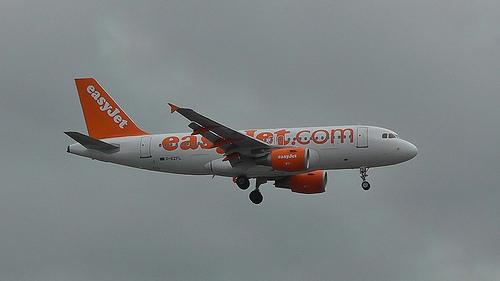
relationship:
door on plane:
[353, 127, 370, 149] [59, 76, 434, 188]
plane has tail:
[59, 76, 420, 205] [88, 80, 128, 130]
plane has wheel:
[59, 76, 434, 188] [246, 188, 264, 206]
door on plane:
[138, 134, 154, 159] [53, 64, 423, 208]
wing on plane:
[171, 109, 276, 161] [48, 86, 380, 209]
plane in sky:
[59, 76, 420, 205] [0, 2, 497, 279]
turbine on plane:
[269, 137, 314, 169] [67, 74, 419, 204]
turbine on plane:
[287, 167, 330, 194] [67, 74, 419, 204]